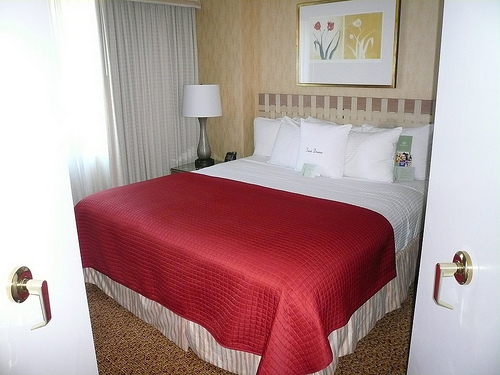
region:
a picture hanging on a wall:
[263, 7, 410, 120]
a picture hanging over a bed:
[278, 1, 408, 124]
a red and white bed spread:
[75, 172, 397, 344]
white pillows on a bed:
[244, 120, 423, 197]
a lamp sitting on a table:
[170, 80, 246, 190]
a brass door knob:
[410, 241, 475, 336]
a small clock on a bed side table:
[224, 136, 254, 174]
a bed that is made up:
[104, 122, 397, 329]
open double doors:
[40, 121, 472, 373]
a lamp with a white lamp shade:
[173, 78, 221, 171]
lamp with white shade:
[176, 72, 223, 163]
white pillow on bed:
[296, 118, 347, 176]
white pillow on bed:
[344, 126, 398, 187]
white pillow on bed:
[258, 118, 299, 163]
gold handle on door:
[421, 249, 471, 316]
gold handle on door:
[13, 267, 81, 342]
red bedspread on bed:
[103, 170, 377, 299]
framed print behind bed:
[282, 3, 414, 86]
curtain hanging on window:
[100, 2, 200, 173]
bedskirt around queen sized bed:
[158, 320, 243, 365]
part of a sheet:
[219, 247, 279, 317]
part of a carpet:
[122, 334, 154, 364]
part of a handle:
[13, 270, 70, 342]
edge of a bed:
[151, 224, 211, 266]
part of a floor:
[96, 311, 149, 368]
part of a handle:
[421, 267, 456, 306]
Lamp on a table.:
[172, 70, 266, 185]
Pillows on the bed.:
[220, 96, 459, 192]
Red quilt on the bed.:
[76, 143, 343, 371]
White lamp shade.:
[159, 62, 226, 131]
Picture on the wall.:
[272, 10, 439, 133]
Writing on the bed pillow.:
[268, 111, 353, 187]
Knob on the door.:
[410, 218, 462, 303]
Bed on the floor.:
[81, 52, 401, 369]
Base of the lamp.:
[175, 112, 277, 189]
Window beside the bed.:
[65, 6, 293, 222]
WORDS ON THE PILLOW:
[305, 148, 321, 157]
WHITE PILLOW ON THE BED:
[345, 128, 383, 178]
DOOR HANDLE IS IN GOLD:
[426, 265, 453, 307]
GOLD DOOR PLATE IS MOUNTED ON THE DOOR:
[450, 243, 477, 284]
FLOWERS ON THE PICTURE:
[307, 16, 337, 58]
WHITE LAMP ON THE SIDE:
[180, 83, 225, 159]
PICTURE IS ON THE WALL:
[285, 1, 412, 86]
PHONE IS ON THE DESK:
[221, 153, 241, 160]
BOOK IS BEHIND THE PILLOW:
[397, 132, 413, 177]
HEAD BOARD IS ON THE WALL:
[341, 99, 365, 122]